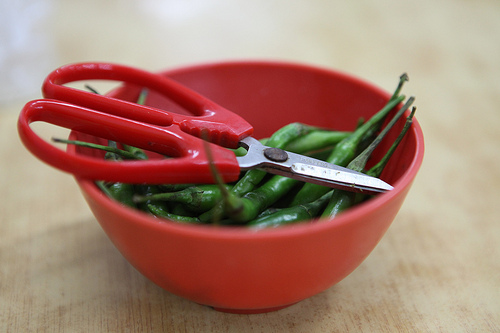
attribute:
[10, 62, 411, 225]
shears — small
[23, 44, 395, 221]
shears — metal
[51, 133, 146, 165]
pepper — green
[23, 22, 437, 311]
bowl — red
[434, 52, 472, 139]
woodentable — wooden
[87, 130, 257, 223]
handle — red, scissor's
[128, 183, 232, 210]
pepper — green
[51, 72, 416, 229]
green beans — green 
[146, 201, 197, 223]
pepper — green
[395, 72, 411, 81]
bean — green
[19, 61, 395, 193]
shears — red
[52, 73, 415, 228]
beans — green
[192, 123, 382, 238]
pepper — green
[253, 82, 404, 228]
beans — green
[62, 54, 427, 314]
bowl — red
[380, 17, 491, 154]
table — unfinished, pale, wooden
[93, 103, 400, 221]
beans — green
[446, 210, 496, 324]
surface — wooden table 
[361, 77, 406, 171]
edge — withered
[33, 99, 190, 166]
handles — red